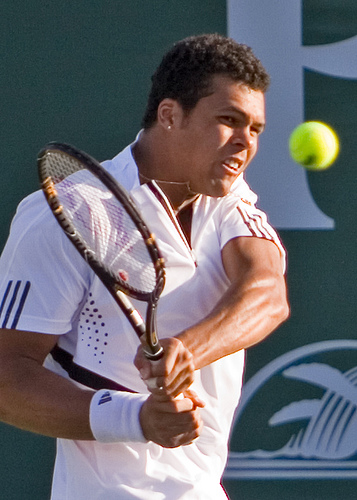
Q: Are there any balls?
A: Yes, there is a ball.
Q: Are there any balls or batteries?
A: Yes, there is a ball.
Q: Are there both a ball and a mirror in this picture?
A: No, there is a ball but no mirrors.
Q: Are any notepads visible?
A: No, there are no notepads.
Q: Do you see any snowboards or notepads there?
A: No, there are no notepads or snowboards.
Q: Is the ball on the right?
A: Yes, the ball is on the right of the image.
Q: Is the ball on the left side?
A: No, the ball is on the right of the image.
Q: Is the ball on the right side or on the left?
A: The ball is on the right of the image.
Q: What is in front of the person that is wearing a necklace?
A: The ball is in front of the man.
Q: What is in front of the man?
A: The ball is in front of the man.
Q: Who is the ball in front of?
A: The ball is in front of the man.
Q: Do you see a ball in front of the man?
A: Yes, there is a ball in front of the man.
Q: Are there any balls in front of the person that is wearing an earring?
A: Yes, there is a ball in front of the man.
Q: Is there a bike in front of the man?
A: No, there is a ball in front of the man.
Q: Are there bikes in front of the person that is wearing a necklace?
A: No, there is a ball in front of the man.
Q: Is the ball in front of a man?
A: Yes, the ball is in front of a man.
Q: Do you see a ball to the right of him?
A: Yes, there is a ball to the right of the man.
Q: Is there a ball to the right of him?
A: Yes, there is a ball to the right of the man.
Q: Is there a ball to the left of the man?
A: No, the ball is to the right of the man.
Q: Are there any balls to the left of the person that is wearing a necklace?
A: No, the ball is to the right of the man.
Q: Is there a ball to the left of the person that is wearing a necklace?
A: No, the ball is to the right of the man.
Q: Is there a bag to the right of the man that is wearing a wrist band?
A: No, there is a ball to the right of the man.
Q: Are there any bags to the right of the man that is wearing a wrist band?
A: No, there is a ball to the right of the man.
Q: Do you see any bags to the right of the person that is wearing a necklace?
A: No, there is a ball to the right of the man.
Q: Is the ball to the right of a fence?
A: No, the ball is to the right of the man.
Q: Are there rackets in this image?
A: Yes, there is a racket.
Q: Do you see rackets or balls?
A: Yes, there is a racket.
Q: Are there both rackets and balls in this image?
A: Yes, there are both a racket and a ball.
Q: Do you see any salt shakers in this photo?
A: No, there are no salt shakers.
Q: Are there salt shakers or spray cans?
A: No, there are no salt shakers or spray cans.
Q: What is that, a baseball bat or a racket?
A: That is a racket.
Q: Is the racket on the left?
A: Yes, the racket is on the left of the image.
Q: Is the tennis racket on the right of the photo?
A: No, the tennis racket is on the left of the image.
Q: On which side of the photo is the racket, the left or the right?
A: The racket is on the left of the image.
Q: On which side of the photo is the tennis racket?
A: The tennis racket is on the left of the image.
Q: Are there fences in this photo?
A: No, there are no fences.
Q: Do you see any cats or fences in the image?
A: No, there are no fences or cats.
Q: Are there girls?
A: No, there are no girls.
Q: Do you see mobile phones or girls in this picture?
A: No, there are no girls or mobile phones.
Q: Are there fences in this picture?
A: No, there are no fences.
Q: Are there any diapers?
A: No, there are no diapers.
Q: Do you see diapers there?
A: No, there are no diapers.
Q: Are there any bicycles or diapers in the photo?
A: No, there are no diapers or bicycles.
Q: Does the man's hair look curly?
A: Yes, the hair is curly.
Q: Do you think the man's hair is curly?
A: Yes, the hair is curly.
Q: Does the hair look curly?
A: Yes, the hair is curly.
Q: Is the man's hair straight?
A: No, the hair is curly.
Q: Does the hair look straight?
A: No, the hair is curly.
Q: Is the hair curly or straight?
A: The hair is curly.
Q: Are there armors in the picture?
A: No, there are no armors.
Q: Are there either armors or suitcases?
A: No, there are no armors or suitcases.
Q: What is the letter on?
A: The letter is on the wall.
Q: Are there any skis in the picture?
A: No, there are no skis.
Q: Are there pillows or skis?
A: No, there are no skis or pillows.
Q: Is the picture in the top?
A: No, the picture is in the bottom of the image.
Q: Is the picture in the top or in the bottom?
A: The picture is in the bottom of the image.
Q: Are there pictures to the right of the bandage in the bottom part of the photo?
A: Yes, there is a picture to the right of the bandage.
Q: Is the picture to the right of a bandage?
A: Yes, the picture is to the right of a bandage.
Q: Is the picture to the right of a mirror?
A: No, the picture is to the right of a bandage.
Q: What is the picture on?
A: The picture is on the wall.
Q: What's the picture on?
A: The picture is on the wall.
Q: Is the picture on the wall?
A: Yes, the picture is on the wall.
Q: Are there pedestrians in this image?
A: No, there are no pedestrians.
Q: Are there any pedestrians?
A: No, there are no pedestrians.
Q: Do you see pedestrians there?
A: No, there are no pedestrians.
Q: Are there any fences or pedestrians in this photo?
A: No, there are no pedestrians or fences.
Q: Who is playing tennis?
A: The man is playing tennis.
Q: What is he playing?
A: The man is playing tennis.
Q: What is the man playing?
A: The man is playing tennis.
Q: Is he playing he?
A: Yes, the man is playing tennis.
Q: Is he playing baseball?
A: No, the man is playing tennis.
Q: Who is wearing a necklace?
A: The man is wearing a necklace.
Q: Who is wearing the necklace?
A: The man is wearing a necklace.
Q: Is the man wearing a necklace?
A: Yes, the man is wearing a necklace.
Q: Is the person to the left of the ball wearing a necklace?
A: Yes, the man is wearing a necklace.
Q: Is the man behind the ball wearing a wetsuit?
A: No, the man is wearing a necklace.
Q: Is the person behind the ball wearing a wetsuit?
A: No, the man is wearing a necklace.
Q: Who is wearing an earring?
A: The man is wearing an earring.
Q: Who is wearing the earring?
A: The man is wearing an earring.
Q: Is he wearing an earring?
A: Yes, the man is wearing an earring.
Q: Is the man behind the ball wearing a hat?
A: No, the man is wearing an earring.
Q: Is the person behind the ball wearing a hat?
A: No, the man is wearing an earring.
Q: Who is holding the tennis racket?
A: The man is holding the tennis racket.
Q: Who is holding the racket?
A: The man is holding the tennis racket.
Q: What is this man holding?
A: The man is holding the tennis racket.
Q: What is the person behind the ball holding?
A: The man is holding the tennis racket.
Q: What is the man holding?
A: The man is holding the tennis racket.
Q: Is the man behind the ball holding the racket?
A: Yes, the man is holding the racket.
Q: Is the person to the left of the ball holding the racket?
A: Yes, the man is holding the racket.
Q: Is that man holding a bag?
A: No, the man is holding the racket.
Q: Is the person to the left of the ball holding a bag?
A: No, the man is holding the racket.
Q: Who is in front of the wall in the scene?
A: The man is in front of the wall.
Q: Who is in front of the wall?
A: The man is in front of the wall.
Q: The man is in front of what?
A: The man is in front of the wall.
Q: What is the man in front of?
A: The man is in front of the wall.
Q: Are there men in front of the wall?
A: Yes, there is a man in front of the wall.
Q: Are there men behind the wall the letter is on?
A: No, the man is in front of the wall.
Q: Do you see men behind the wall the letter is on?
A: No, the man is in front of the wall.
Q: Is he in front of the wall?
A: Yes, the man is in front of the wall.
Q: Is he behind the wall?
A: No, the man is in front of the wall.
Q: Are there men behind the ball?
A: Yes, there is a man behind the ball.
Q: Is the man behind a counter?
A: No, the man is behind the ball.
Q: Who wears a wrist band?
A: The man wears a wrist band.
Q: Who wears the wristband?
A: The man wears a wrist band.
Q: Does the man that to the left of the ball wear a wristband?
A: Yes, the man wears a wristband.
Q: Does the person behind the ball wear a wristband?
A: Yes, the man wears a wristband.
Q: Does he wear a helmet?
A: No, the man wears a wristband.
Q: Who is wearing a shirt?
A: The man is wearing a shirt.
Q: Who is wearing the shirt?
A: The man is wearing a shirt.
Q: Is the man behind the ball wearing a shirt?
A: Yes, the man is wearing a shirt.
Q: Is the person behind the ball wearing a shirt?
A: Yes, the man is wearing a shirt.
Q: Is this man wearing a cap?
A: No, the man is wearing a shirt.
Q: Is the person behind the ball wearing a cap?
A: No, the man is wearing a shirt.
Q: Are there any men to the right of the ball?
A: No, the man is to the left of the ball.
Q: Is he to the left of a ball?
A: Yes, the man is to the left of a ball.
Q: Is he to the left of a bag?
A: No, the man is to the left of a ball.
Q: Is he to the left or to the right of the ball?
A: The man is to the left of the ball.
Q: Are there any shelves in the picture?
A: No, there are no shelves.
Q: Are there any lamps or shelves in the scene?
A: No, there are no shelves or lamps.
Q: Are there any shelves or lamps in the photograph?
A: No, there are no shelves or lamps.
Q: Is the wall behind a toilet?
A: No, the wall is behind the man.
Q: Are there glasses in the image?
A: No, there are no glasses.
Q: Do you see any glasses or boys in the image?
A: No, there are no glasses or boys.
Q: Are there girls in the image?
A: No, there are no girls.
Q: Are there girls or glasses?
A: No, there are no girls or glasses.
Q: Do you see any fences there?
A: No, there are no fences.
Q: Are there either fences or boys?
A: No, there are no fences or boys.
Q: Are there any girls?
A: No, there are no girls.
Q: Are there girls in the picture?
A: No, there are no girls.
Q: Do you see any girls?
A: No, there are no girls.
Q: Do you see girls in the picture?
A: No, there are no girls.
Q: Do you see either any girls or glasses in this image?
A: No, there are no girls or glasses.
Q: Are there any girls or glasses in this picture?
A: No, there are no girls or glasses.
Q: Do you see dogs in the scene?
A: No, there are no dogs.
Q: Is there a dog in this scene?
A: No, there are no dogs.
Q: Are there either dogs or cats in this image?
A: No, there are no dogs or cats.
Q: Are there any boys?
A: No, there are no boys.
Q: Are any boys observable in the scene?
A: No, there are no boys.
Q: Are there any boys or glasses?
A: No, there are no boys or glasses.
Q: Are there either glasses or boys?
A: No, there are no boys or glasses.